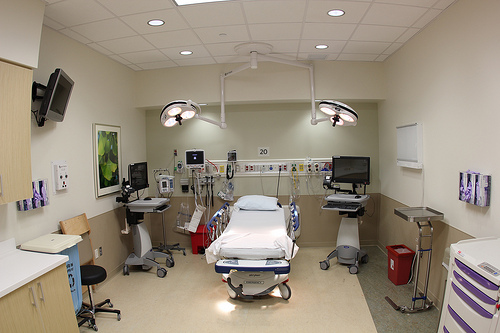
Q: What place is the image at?
A: It is at the hospital.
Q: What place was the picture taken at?
A: It was taken at the hospital.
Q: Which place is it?
A: It is a hospital.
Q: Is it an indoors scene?
A: Yes, it is indoors.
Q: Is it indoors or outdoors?
A: It is indoors.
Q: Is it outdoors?
A: No, it is indoors.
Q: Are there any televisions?
A: Yes, there is a television.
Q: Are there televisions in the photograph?
A: Yes, there is a television.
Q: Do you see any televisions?
A: Yes, there is a television.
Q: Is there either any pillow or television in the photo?
A: Yes, there is a television.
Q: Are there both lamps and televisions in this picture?
A: Yes, there are both a television and a lamp.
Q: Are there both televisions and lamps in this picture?
A: Yes, there are both a television and a lamp.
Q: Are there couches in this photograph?
A: No, there are no couches.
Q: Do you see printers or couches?
A: No, there are no couches or printers.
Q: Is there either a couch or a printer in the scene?
A: No, there are no couches or printers.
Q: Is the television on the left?
A: Yes, the television is on the left of the image.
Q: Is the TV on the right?
A: No, the TV is on the left of the image.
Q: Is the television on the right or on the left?
A: The television is on the left of the image.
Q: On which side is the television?
A: The television is on the left of the image.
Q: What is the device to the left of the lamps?
A: The device is a television.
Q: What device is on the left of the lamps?
A: The device is a television.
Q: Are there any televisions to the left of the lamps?
A: Yes, there is a television to the left of the lamps.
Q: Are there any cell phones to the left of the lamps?
A: No, there is a television to the left of the lamps.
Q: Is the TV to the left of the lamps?
A: Yes, the TV is to the left of the lamps.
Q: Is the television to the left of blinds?
A: No, the television is to the left of the lamps.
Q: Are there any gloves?
A: Yes, there are gloves.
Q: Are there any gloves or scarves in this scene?
A: Yes, there are gloves.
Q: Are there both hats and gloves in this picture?
A: No, there are gloves but no hats.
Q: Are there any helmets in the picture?
A: No, there are no helmets.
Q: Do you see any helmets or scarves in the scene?
A: No, there are no helmets or scarves.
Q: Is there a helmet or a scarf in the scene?
A: No, there are no helmets or scarves.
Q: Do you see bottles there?
A: No, there are no bottles.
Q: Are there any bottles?
A: No, there are no bottles.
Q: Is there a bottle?
A: No, there are no bottles.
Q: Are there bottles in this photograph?
A: No, there are no bottles.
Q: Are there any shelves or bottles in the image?
A: No, there are no bottles or shelves.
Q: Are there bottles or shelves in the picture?
A: No, there are no bottles or shelves.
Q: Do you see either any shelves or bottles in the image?
A: No, there are no bottles or shelves.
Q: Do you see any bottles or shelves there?
A: No, there are no bottles or shelves.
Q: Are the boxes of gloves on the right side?
A: Yes, the boxes are on the right of the image.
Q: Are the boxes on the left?
A: No, the boxes are on the right of the image.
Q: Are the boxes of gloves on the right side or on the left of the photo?
A: The boxes are on the right of the image.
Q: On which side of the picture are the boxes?
A: The boxes are on the right of the image.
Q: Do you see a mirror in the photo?
A: No, there are no mirrors.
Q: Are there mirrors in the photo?
A: No, there are no mirrors.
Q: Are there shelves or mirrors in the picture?
A: No, there are no mirrors or shelves.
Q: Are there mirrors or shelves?
A: No, there are no mirrors or shelves.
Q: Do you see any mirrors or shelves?
A: No, there are no mirrors or shelves.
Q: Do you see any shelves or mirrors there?
A: No, there are no mirrors or shelves.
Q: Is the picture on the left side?
A: Yes, the picture is on the left of the image.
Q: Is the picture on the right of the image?
A: No, the picture is on the left of the image.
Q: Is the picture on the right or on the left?
A: The picture is on the left of the image.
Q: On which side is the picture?
A: The picture is on the left of the image.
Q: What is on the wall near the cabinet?
A: The picture is on the wall.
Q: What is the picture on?
A: The picture is on the wall.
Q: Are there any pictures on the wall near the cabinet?
A: Yes, there is a picture on the wall.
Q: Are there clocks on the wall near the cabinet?
A: No, there is a picture on the wall.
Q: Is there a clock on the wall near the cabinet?
A: No, there is a picture on the wall.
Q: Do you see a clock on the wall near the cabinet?
A: No, there is a picture on the wall.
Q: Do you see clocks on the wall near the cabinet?
A: No, there is a picture on the wall.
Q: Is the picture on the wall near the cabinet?
A: Yes, the picture is on the wall.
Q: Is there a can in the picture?
A: Yes, there is a can.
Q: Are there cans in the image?
A: Yes, there is a can.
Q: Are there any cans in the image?
A: Yes, there is a can.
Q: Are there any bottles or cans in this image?
A: Yes, there is a can.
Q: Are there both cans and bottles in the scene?
A: No, there is a can but no bottles.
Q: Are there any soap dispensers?
A: No, there are no soap dispensers.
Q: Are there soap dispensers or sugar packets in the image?
A: No, there are no soap dispensers or sugar packets.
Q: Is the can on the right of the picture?
A: Yes, the can is on the right of the image.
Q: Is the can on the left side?
A: No, the can is on the right of the image.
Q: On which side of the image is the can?
A: The can is on the right of the image.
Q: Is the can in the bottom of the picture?
A: Yes, the can is in the bottom of the image.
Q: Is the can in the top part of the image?
A: No, the can is in the bottom of the image.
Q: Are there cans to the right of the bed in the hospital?
A: Yes, there is a can to the right of the bed.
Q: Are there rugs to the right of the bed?
A: No, there is a can to the right of the bed.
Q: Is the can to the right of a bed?
A: Yes, the can is to the right of a bed.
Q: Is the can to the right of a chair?
A: No, the can is to the right of a bed.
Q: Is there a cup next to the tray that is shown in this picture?
A: No, there is a can next to the tray.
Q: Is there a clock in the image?
A: No, there are no clocks.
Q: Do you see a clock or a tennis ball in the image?
A: No, there are no clocks or tennis balls.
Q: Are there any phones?
A: No, there are no phones.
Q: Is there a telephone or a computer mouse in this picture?
A: No, there are no phones or computer mice.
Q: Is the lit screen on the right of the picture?
A: Yes, the screen is on the right of the image.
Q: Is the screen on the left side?
A: No, the screen is on the right of the image.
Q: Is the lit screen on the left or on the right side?
A: The screen is on the right of the image.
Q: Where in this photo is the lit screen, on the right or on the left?
A: The screen is on the right of the image.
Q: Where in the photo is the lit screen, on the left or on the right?
A: The screen is on the right of the image.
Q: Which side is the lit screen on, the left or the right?
A: The screen is on the right of the image.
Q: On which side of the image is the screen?
A: The screen is on the right of the image.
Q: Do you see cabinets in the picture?
A: Yes, there is a cabinet.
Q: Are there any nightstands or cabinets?
A: Yes, there is a cabinet.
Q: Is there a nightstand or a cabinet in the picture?
A: Yes, there is a cabinet.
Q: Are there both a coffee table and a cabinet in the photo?
A: No, there is a cabinet but no coffee tables.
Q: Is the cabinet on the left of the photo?
A: Yes, the cabinet is on the left of the image.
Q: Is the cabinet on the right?
A: No, the cabinet is on the left of the image.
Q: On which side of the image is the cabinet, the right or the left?
A: The cabinet is on the left of the image.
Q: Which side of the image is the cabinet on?
A: The cabinet is on the left of the image.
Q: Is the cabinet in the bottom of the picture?
A: Yes, the cabinet is in the bottom of the image.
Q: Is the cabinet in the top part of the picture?
A: No, the cabinet is in the bottom of the image.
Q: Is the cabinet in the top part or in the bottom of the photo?
A: The cabinet is in the bottom of the image.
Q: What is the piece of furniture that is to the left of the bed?
A: The piece of furniture is a cabinet.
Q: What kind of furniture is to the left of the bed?
A: The piece of furniture is a cabinet.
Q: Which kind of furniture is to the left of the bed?
A: The piece of furniture is a cabinet.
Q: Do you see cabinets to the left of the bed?
A: Yes, there is a cabinet to the left of the bed.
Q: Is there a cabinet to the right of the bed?
A: No, the cabinet is to the left of the bed.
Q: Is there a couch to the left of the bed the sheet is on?
A: No, there is a cabinet to the left of the bed.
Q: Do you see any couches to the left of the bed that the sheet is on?
A: No, there is a cabinet to the left of the bed.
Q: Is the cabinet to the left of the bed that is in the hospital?
A: Yes, the cabinet is to the left of the bed.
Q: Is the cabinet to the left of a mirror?
A: No, the cabinet is to the left of the bed.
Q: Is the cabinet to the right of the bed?
A: No, the cabinet is to the left of the bed.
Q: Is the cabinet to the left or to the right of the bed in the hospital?
A: The cabinet is to the left of the bed.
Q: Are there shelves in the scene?
A: No, there are no shelves.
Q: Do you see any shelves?
A: No, there are no shelves.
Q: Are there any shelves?
A: No, there are no shelves.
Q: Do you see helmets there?
A: No, there are no helmets.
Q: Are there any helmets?
A: No, there are no helmets.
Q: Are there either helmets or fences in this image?
A: No, there are no helmets or fences.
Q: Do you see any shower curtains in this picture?
A: No, there are no shower curtains.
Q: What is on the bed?
A: The sheet is on the bed.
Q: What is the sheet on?
A: The sheet is on the bed.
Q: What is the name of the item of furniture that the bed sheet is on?
A: The piece of furniture is a bed.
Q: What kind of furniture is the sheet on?
A: The bed sheet is on the bed.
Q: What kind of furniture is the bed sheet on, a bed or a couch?
A: The bed sheet is on a bed.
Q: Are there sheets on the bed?
A: Yes, there is a sheet on the bed.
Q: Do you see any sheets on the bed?
A: Yes, there is a sheet on the bed.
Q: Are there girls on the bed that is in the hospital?
A: No, there is a sheet on the bed.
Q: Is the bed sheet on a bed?
A: Yes, the bed sheet is on a bed.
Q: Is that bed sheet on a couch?
A: No, the bed sheet is on a bed.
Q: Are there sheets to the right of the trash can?
A: Yes, there is a sheet to the right of the trash can.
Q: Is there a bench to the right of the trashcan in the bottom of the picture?
A: No, there is a sheet to the right of the trash bin.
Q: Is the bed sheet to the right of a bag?
A: No, the bed sheet is to the right of the trash can.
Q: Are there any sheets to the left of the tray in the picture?
A: Yes, there is a sheet to the left of the tray.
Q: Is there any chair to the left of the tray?
A: No, there is a sheet to the left of the tray.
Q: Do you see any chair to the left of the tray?
A: No, there is a sheet to the left of the tray.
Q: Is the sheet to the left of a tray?
A: Yes, the sheet is to the left of a tray.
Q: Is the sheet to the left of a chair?
A: No, the sheet is to the left of a tray.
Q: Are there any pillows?
A: Yes, there is a pillow.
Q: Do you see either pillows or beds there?
A: Yes, there is a pillow.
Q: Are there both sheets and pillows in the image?
A: Yes, there are both a pillow and a sheet.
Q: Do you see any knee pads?
A: No, there are no knee pads.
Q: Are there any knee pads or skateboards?
A: No, there are no knee pads or skateboards.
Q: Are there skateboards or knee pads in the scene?
A: No, there are no knee pads or skateboards.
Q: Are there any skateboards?
A: No, there are no skateboards.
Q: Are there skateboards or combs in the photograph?
A: No, there are no skateboards or combs.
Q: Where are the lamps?
A: The lamps are on the hospital.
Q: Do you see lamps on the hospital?
A: Yes, there are lamps on the hospital.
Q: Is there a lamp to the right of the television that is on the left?
A: Yes, there are lamps to the right of the television.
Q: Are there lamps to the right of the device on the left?
A: Yes, there are lamps to the right of the television.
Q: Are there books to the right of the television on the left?
A: No, there are lamps to the right of the TV.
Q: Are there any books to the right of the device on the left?
A: No, there are lamps to the right of the TV.